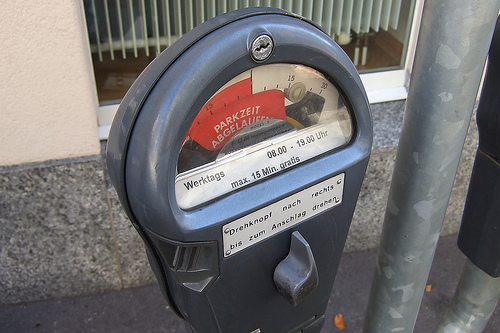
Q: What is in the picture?
A: Parking meter.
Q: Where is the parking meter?
A: On the sidewalk.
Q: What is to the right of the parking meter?
A: A pole.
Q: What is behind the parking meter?
A: A building.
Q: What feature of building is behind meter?
A: A window.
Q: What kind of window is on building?
A: Glass window.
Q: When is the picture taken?
A: Daytime.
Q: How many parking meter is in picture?
A: Two.